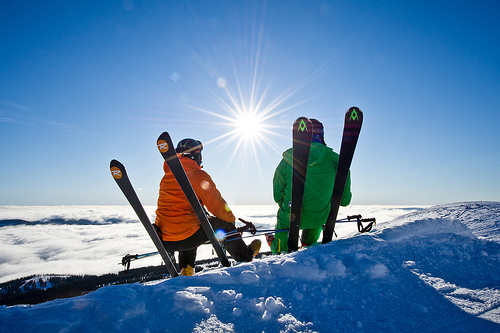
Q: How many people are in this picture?
A: Two.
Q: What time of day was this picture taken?
A: Daytime.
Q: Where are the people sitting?
A: On their ski poles.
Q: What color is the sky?
A: Blue.